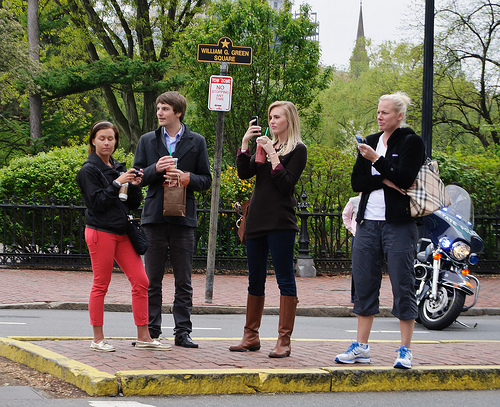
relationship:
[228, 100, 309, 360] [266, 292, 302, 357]
person wearing boot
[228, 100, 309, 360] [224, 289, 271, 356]
person wearing boot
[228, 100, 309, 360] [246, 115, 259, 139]
person holding phone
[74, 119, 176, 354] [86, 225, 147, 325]
pedestrian wearing jean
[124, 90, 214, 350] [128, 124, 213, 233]
pedestrian wearing coat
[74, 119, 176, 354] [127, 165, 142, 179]
pedestrian using cellphone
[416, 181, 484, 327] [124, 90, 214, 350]
motorcycle behind pedestrian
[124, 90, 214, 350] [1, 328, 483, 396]
pedestrian in meridian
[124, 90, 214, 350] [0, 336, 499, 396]
pedestrian standing on median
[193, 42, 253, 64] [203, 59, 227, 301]
sign on pole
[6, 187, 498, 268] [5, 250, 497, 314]
fence by sidewalk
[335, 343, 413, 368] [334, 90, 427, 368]
sneakers on person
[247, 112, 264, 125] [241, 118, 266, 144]
phone in hand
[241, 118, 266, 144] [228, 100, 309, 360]
hand of person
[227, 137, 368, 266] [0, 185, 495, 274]
bush behind fence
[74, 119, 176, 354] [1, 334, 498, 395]
pedestrian on sidewalk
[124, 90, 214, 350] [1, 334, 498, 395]
pedestrian on sidewalk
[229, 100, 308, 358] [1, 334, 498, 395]
person on sidewalk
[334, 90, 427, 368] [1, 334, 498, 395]
person on sidewalk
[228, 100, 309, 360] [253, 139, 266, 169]
person holding smoothie cup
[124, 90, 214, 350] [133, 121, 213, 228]
pedestrian wearing coat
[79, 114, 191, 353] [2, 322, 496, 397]
pedestrian standing in median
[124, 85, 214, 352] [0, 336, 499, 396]
pedestrian in median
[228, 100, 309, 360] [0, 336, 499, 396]
person in median